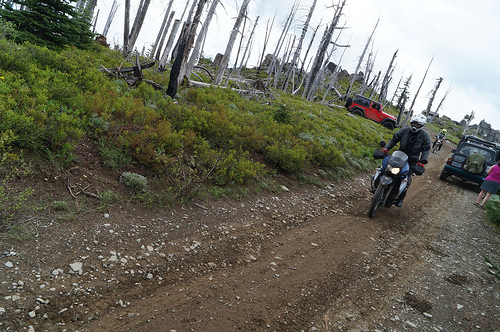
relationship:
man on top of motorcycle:
[432, 128, 447, 150] [433, 135, 449, 153]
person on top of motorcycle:
[374, 113, 430, 207] [367, 142, 424, 217]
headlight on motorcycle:
[385, 164, 400, 174] [367, 134, 441, 239]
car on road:
[441, 135, 498, 188] [0, 144, 498, 328]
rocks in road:
[2, 177, 499, 330] [0, 144, 498, 328]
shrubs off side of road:
[0, 40, 408, 196] [2, 123, 495, 325]